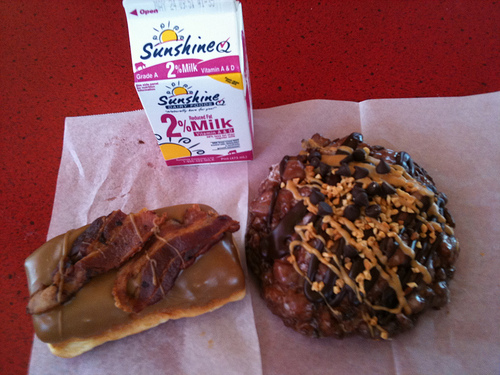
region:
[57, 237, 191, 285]
two pieces of bacon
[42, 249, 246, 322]
chocolate frosting on donut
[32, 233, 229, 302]
bacon on top of donut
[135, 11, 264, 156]
carton of milk next to donuts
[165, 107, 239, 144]
2% Milk is written in purple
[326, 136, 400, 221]
donut has has chocolate chips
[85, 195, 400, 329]
two donuts on the paper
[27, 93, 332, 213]
donuts and milk are on the table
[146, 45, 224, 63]
Sunshine is written in blue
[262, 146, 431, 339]
donut is round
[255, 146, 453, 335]
A messy round donut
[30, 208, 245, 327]
A donut with two strips of bacon.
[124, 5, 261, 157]
A container of milk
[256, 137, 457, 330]
There are multiple toppings on the donut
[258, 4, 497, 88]
The table is red with black flecks.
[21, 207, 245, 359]
The donut is rectangular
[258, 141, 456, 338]
The donut is in the shape of a circle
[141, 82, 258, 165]
There are two suns on the carton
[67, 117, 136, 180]
The corner of the paper is white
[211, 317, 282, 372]
This portion of the paper is wrinkled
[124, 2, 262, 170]
white and pink milk pot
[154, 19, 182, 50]
little sunshine symbol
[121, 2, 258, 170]
sunshine 2% milk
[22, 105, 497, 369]
white napkin where food is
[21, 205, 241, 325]
two slices of bacon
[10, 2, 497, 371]
red table under napkin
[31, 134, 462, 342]
fried food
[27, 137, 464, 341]
two pieces of food on a napkin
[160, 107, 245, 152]
fuchsia letters in white pot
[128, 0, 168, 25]
open here fuchsia letters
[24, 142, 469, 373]
two pieces of pastry on white paper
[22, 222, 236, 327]
bacon topping on pastry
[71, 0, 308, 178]
small carton of milk on white paper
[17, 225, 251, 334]
maple frosting on pastry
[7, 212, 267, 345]
oblong shape of pastry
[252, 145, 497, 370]
round pastry on paper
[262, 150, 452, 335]
choclate and caramel dirzzled on top of pastry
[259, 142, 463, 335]
crunchy brown topping on pastry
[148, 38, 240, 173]
yellow suns on milk carton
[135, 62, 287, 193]
pink, white, blue, and yellow carton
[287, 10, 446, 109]
The table is red with black speckles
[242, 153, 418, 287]
icing on top of pastry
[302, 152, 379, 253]
The top has nuts on it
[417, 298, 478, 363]
The paper is white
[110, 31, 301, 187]
The milk carton is 2%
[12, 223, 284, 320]
The doughnut has bacon on it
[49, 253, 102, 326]
The icing is carmel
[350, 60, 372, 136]
the napkin is creased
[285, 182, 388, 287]
The top is chocolate and carmel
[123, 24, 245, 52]
The milk is sunshine brand